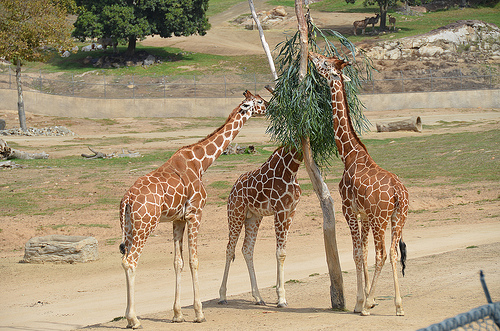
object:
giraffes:
[118, 89, 269, 329]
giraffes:
[218, 142, 303, 306]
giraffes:
[308, 51, 408, 314]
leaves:
[1, 0, 78, 66]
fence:
[395, 301, 497, 330]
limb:
[264, 5, 373, 176]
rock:
[20, 233, 99, 264]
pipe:
[374, 117, 425, 133]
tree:
[1, 2, 80, 134]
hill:
[349, 19, 498, 70]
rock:
[8, 123, 74, 136]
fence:
[1, 74, 500, 99]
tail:
[119, 201, 129, 254]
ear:
[332, 56, 342, 70]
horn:
[242, 89, 252, 98]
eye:
[256, 98, 262, 106]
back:
[164, 143, 193, 172]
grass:
[1, 128, 500, 211]